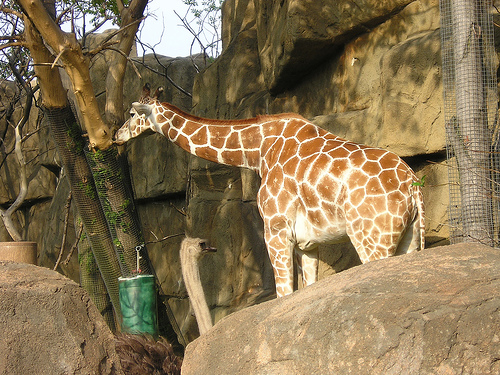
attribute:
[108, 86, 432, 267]
giraffe — close, white, spotted, yellow, tan, brown, wide, tall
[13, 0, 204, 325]
tree — thin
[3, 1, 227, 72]
sky — bright, white, open, clear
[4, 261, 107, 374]
rock — close, large, brown, gray, round, big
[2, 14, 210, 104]
branches — leafless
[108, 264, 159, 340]
bucket — green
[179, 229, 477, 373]
rock — brown, gray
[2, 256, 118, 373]
rock — gray, brown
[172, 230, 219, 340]
ostrich — gray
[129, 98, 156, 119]
ear — white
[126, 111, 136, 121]
eye — dark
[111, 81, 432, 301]
giraffe — brown, white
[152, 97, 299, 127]
hair — brown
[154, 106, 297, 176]
neck — long